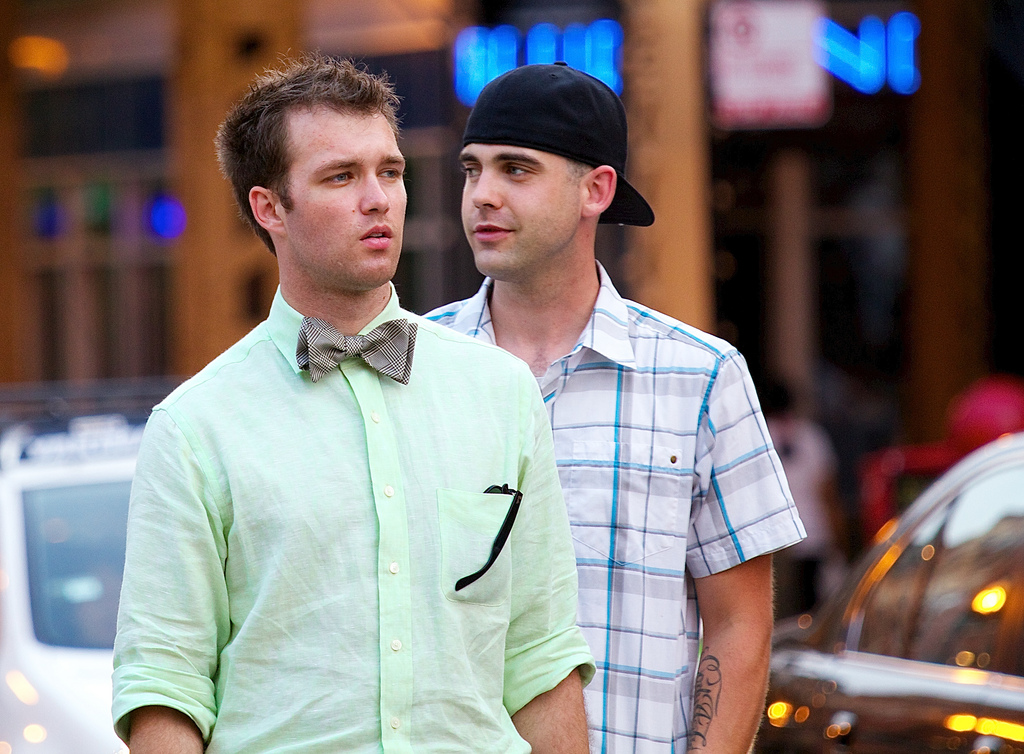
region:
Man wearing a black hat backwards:
[421, 70, 892, 671]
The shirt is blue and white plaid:
[437, 260, 845, 747]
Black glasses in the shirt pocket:
[74, 151, 641, 648]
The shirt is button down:
[127, 252, 580, 743]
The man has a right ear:
[190, 91, 462, 374]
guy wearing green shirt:
[106, 59, 596, 749]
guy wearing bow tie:
[113, 53, 601, 752]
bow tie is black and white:
[294, 316, 419, 387]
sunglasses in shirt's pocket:
[104, 285, 595, 751]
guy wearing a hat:
[419, 60, 808, 750]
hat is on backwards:
[455, 51, 658, 230]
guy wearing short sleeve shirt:
[423, 56, 813, 750]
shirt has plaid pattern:
[423, 268, 804, 752]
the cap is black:
[460, 56, 660, 230]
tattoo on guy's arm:
[429, 54, 796, 751]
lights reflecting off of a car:
[761, 523, 1019, 739]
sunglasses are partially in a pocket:
[451, 485, 524, 597]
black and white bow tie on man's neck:
[296, 318, 424, 380]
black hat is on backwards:
[464, 56, 655, 227]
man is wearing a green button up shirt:
[116, 50, 594, 750]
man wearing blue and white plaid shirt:
[414, 63, 813, 747]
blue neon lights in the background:
[446, 12, 921, 115]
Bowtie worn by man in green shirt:
[273, 303, 442, 396]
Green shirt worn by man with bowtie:
[105, 268, 600, 749]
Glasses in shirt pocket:
[430, 462, 541, 627]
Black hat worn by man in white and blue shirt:
[447, 57, 669, 235]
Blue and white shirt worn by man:
[397, 256, 787, 750]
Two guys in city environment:
[74, 40, 780, 750]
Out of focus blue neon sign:
[419, 6, 952, 140]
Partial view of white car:
[4, 369, 249, 749]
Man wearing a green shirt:
[93, 45, 593, 744]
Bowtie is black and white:
[286, 309, 420, 398]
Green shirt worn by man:
[93, 279, 596, 751]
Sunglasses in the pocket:
[453, 474, 526, 604]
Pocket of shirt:
[446, 492, 520, 601]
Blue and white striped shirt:
[378, 259, 808, 751]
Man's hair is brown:
[215, 53, 413, 253]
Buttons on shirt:
[361, 354, 404, 750]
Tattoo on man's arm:
[686, 648, 729, 750]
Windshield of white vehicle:
[14, 464, 160, 651]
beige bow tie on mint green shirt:
[288, 311, 426, 388]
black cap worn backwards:
[461, 44, 655, 234]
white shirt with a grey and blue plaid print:
[425, 265, 803, 747]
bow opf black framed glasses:
[452, 481, 528, 595]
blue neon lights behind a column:
[446, 4, 924, 119]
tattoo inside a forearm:
[683, 648, 723, 751]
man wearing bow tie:
[83, 45, 609, 748]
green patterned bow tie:
[286, 296, 414, 388]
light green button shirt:
[98, 300, 595, 747]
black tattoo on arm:
[687, 635, 727, 750]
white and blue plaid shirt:
[403, 237, 789, 744]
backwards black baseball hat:
[449, 53, 665, 228]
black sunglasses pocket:
[444, 464, 522, 608]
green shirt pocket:
[438, 489, 512, 604]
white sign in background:
[700, 4, 844, 134]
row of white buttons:
[345, 364, 413, 737]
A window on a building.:
[129, 261, 174, 388]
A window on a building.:
[81, 266, 116, 381]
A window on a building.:
[32, 264, 59, 405]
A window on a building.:
[29, 196, 62, 239]